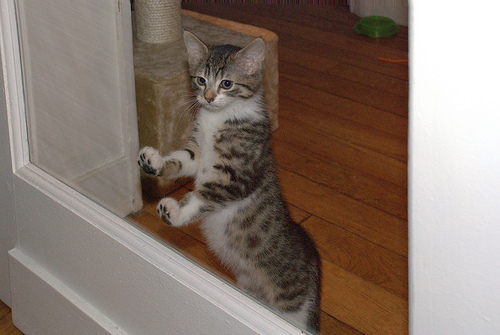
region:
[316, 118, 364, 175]
Wooden floor in the house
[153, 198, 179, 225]
Left paw of cat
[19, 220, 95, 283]
White door that is covering the house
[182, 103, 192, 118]
Small patch of white whiskers of the cat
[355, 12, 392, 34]
Small green bowl inside the house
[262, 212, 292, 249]
Gray and black fur of the cat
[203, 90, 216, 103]
Light nose of cat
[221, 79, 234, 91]
Left eye of cat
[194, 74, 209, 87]
Right eye of cat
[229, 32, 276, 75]
Left ear of cat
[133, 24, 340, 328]
a gray and white tabby kitten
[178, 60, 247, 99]
soft blue eyes of a kitten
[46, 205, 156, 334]
a white wooden door frame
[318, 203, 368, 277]
brown wooden slats on the floor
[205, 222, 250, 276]
white fur on the underbelly of a kitten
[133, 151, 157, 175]
black pads of a kitten on glass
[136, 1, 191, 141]
a brown cat scratching pad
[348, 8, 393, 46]
a plastic water bowl on the floor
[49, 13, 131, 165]
the white inner wall of a room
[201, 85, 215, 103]
the light brown nose of a kitten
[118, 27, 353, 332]
this is a cat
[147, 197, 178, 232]
this is the left paw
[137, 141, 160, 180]
this is the right paw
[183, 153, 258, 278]
this is a cat belly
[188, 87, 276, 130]
this is cat neck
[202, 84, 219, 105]
this cat is a nose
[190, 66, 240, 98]
these are cat eyes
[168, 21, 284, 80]
these are cat eyes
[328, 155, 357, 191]
this is a brown floor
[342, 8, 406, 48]
Water bowl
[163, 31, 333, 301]
Kitten standing against the door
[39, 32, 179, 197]
The door is made of glass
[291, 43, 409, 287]
The floors are made of wood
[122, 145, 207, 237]
The kittens front paws are flat against the glass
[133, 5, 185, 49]
Scratching post for the kitten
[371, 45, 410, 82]
Orange object by the water bowl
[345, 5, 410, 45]
The water bowl is nearly full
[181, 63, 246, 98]
The cat's eyes are open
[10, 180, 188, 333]
The base of the door is white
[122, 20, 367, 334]
grey and white cat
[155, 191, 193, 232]
paw of a cat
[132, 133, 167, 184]
paw of a cat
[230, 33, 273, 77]
ear of a cat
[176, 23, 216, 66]
ear of a cat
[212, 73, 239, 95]
eye of a cat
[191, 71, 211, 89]
eye of a cat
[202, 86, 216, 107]
nose of a cat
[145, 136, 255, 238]
front leg of a cat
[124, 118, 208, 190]
front leg of a cat